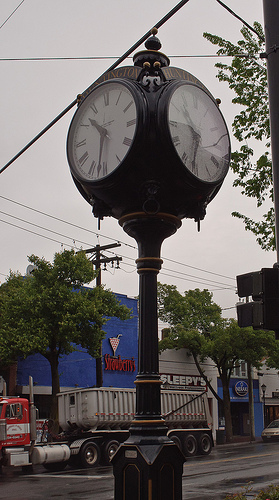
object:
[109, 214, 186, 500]
post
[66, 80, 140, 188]
clock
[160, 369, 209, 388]
sign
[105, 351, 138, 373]
logo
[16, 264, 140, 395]
building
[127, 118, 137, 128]
number 3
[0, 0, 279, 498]
scene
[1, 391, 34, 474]
truck cab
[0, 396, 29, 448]
cab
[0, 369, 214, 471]
truck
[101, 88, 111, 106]
12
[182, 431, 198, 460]
tire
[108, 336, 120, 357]
glass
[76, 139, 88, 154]
numeral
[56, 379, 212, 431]
white box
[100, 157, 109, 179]
6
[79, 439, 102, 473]
wheel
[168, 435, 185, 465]
wheel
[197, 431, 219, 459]
wheel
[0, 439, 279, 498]
ground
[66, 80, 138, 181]
face